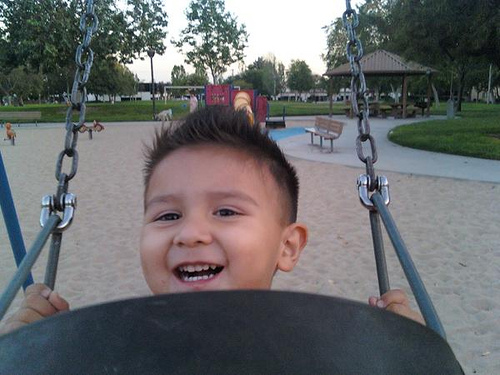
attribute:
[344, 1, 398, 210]
chain — metal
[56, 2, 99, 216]
chain — metal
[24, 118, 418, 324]
boy — smiling, laughing, young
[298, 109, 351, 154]
bench — wooden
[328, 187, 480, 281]
sand — brown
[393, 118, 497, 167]
grassy area — green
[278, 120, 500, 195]
sidewalk — cemented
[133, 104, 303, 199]
hair — brown, black, dark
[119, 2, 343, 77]
sky — white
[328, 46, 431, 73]
roof — brown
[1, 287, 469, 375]
tire — black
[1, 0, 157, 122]
trees — dark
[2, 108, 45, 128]
bench — wooden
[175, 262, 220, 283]
teeth — white